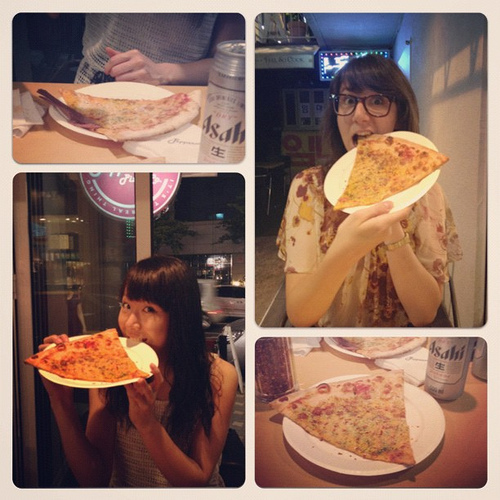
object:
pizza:
[360, 145, 402, 187]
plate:
[327, 133, 431, 212]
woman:
[285, 91, 454, 321]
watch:
[381, 233, 413, 256]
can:
[427, 331, 469, 399]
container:
[260, 347, 289, 394]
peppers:
[270, 373, 284, 384]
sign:
[83, 171, 181, 225]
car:
[204, 275, 248, 321]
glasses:
[336, 90, 391, 118]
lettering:
[95, 201, 127, 216]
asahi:
[427, 343, 464, 358]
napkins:
[140, 145, 177, 166]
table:
[12, 82, 206, 166]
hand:
[337, 202, 407, 257]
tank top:
[127, 23, 180, 50]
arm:
[131, 60, 225, 83]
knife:
[35, 86, 80, 117]